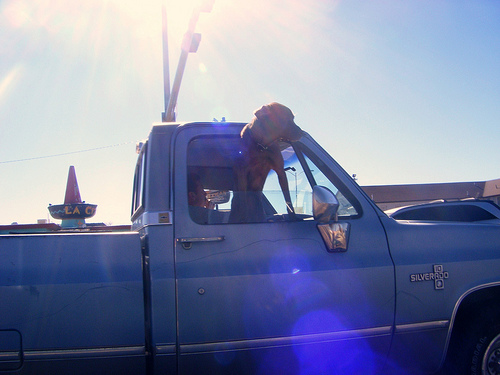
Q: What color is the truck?
A: Blue.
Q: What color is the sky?
A: Light blue.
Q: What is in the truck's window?
A: A dog.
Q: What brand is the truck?
A: A Chevy.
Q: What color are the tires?
A: Black.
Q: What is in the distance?
A: A Mexican restaurant.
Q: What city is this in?
A: New Mexico.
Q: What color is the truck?
A: Blue.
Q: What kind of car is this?
A: Truck.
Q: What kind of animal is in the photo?
A: Dog.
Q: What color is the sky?
A: Blue and white.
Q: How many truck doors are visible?
A: One.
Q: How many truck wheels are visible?
A: One.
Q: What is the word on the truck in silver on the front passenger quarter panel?
A: Silverado.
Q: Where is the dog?
A: Inside truck.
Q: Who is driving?
A: Man.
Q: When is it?
A: Day time.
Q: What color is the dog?
A: Brown.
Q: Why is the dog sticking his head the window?
A: Air.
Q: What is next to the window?
A: Mirror.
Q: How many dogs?
A: 1.